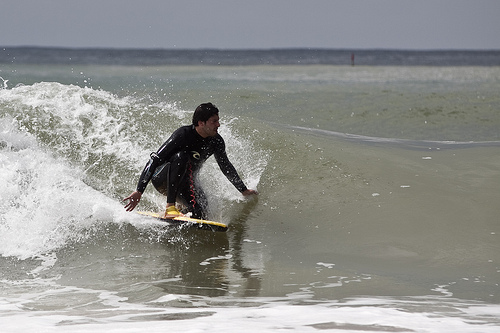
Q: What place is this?
A: It is an ocean.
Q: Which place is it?
A: It is an ocean.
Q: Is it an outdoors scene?
A: Yes, it is outdoors.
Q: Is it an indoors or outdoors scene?
A: It is outdoors.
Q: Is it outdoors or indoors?
A: It is outdoors.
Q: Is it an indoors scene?
A: No, it is outdoors.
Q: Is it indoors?
A: No, it is outdoors.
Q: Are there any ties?
A: No, there are no ties.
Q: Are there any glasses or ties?
A: No, there are no ties or glasses.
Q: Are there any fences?
A: No, there are no fences.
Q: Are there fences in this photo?
A: No, there are no fences.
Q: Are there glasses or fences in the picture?
A: No, there are no fences or glasses.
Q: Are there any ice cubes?
A: No, there are no ice cubes.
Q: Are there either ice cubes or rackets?
A: No, there are no ice cubes or rackets.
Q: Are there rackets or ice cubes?
A: No, there are no ice cubes or rackets.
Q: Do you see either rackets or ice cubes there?
A: No, there are no ice cubes or rackets.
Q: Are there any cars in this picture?
A: No, there are no cars.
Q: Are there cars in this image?
A: No, there are no cars.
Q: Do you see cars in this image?
A: No, there are no cars.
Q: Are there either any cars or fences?
A: No, there are no cars or fences.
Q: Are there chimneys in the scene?
A: No, there are no chimneys.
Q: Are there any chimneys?
A: No, there are no chimneys.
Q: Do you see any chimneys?
A: No, there are no chimneys.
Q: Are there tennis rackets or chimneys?
A: No, there are no chimneys or tennis rackets.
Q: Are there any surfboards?
A: Yes, there is a surfboard.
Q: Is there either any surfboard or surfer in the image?
A: Yes, there is a surfboard.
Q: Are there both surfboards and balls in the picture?
A: No, there is a surfboard but no balls.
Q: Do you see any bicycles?
A: No, there are no bicycles.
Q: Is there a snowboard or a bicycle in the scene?
A: No, there are no bicycles or snowboards.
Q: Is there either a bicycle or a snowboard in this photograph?
A: No, there are no bicycles or snowboards.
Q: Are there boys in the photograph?
A: No, there are no boys.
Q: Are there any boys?
A: No, there are no boys.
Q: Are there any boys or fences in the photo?
A: No, there are no boys or fences.